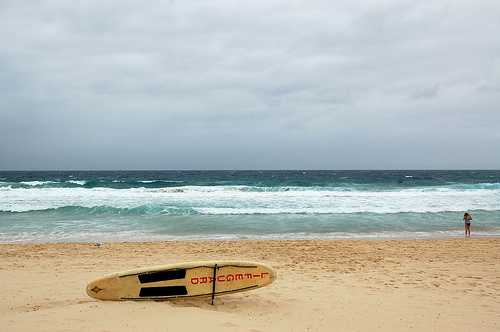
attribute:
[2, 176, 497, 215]
wave — white, heavy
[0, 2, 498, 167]
cloud — thick, gray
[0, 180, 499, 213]
wave cap — white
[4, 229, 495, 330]
sand — brown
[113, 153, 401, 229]
ocean — deep, dark, blue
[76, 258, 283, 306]
surfboard — wood colored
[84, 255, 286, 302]
surfboard — lifeguard, yellow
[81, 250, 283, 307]
flotation device — yellow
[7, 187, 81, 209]
rough surf — wavy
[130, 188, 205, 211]
white waves — blue, ocean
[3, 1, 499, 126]
cloudy sky — gray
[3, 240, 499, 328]
sand — brown, clean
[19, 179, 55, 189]
white water — foamy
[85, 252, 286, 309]
tan surfboard — black and red